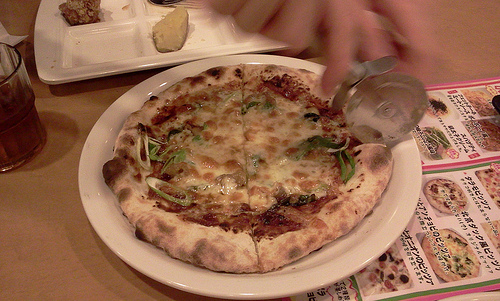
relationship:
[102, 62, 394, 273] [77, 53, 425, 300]
pizza on a plate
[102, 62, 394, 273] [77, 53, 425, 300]
pizza on top of a plate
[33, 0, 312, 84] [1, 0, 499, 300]
tray on table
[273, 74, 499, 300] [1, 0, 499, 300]
menu on table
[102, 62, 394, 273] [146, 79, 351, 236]
pizza has cheese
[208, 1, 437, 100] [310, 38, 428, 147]
hand holding pizza cutter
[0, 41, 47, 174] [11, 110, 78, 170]
cup has a shadow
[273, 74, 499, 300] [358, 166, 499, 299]
menu has many selections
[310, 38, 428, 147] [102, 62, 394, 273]
pizza cutter slicing pizza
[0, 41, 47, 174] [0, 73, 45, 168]
cup has liquid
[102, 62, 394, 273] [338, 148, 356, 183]
pizza has a vegetable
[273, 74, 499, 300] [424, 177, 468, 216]
menu has a picture of pizza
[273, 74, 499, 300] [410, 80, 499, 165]
menu has pictures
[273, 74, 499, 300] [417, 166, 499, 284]
menu has pictures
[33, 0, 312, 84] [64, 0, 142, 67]
plate has squares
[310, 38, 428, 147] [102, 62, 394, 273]
pizza cutter cutting a pizza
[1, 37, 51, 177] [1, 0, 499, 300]
glass on table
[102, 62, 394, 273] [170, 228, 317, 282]
pizza has crust